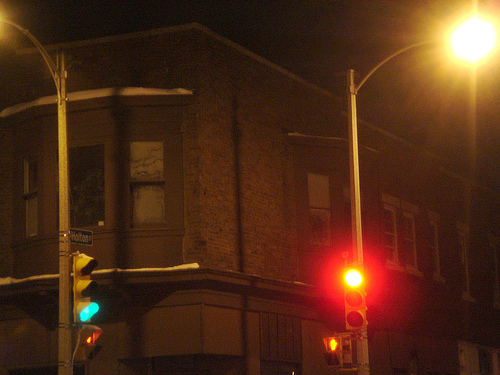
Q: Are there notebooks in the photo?
A: No, there are no notebooks.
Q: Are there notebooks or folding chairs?
A: No, there are no notebooks or folding chairs.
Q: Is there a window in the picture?
A: Yes, there is a window.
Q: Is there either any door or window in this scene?
A: Yes, there is a window.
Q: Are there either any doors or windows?
A: Yes, there is a window.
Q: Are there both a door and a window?
A: No, there is a window but no doors.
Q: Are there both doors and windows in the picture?
A: No, there is a window but no doors.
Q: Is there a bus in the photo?
A: No, there are no buses.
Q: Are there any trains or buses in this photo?
A: No, there are no buses or trains.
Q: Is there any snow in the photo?
A: Yes, there is snow.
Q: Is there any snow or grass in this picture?
A: Yes, there is snow.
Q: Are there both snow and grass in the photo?
A: No, there is snow but no grass.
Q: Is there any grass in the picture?
A: No, there is no grass.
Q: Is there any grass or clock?
A: No, there are no grass or clocks.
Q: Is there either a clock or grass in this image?
A: No, there are no grass or clocks.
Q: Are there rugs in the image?
A: No, there are no rugs.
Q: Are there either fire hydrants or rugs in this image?
A: No, there are no rugs or fire hydrants.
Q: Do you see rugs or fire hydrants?
A: No, there are no rugs or fire hydrants.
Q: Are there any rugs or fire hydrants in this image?
A: No, there are no rugs or fire hydrants.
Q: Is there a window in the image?
A: Yes, there is a window.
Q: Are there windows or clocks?
A: Yes, there is a window.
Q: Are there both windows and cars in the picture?
A: No, there is a window but no cars.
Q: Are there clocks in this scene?
A: No, there are no clocks.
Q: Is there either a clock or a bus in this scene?
A: No, there are no clocks or buses.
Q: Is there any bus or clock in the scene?
A: No, there are no clocks or buses.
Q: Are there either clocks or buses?
A: No, there are no clocks or buses.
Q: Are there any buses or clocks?
A: No, there are no clocks or buses.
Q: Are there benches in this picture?
A: No, there are no benches.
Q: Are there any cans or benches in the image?
A: No, there are no benches or cans.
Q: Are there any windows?
A: Yes, there is a window.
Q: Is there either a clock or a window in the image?
A: Yes, there is a window.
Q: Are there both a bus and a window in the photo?
A: No, there is a window but no buses.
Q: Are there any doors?
A: No, there are no doors.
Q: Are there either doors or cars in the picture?
A: No, there are no doors or cars.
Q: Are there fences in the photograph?
A: No, there are no fences.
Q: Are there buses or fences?
A: No, there are no fences or buses.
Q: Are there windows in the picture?
A: Yes, there is a window.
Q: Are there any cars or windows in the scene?
A: Yes, there is a window.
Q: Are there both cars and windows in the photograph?
A: No, there is a window but no cars.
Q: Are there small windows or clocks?
A: Yes, there is a small window.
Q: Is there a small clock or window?
A: Yes, there is a small window.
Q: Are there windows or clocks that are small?
A: Yes, the window is small.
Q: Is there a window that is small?
A: Yes, there is a small window.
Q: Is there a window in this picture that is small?
A: Yes, there is a window that is small.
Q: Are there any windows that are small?
A: Yes, there is a window that is small.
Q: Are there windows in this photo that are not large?
A: Yes, there is a small window.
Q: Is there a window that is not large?
A: Yes, there is a small window.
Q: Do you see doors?
A: No, there are no doors.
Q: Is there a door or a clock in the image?
A: No, there are no doors or clocks.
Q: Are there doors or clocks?
A: No, there are no doors or clocks.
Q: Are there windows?
A: Yes, there is a window.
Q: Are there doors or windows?
A: Yes, there is a window.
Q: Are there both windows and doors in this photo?
A: No, there is a window but no doors.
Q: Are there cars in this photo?
A: No, there are no cars.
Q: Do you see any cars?
A: No, there are no cars.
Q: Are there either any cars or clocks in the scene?
A: No, there are no cars or clocks.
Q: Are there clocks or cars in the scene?
A: No, there are no cars or clocks.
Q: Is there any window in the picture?
A: Yes, there is a window.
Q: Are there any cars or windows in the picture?
A: Yes, there is a window.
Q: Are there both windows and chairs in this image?
A: No, there is a window but no chairs.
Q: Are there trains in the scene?
A: No, there are no trains.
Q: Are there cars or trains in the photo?
A: No, there are no trains or cars.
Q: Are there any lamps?
A: Yes, there is a lamp.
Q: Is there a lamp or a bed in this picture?
A: Yes, there is a lamp.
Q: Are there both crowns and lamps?
A: No, there is a lamp but no crowns.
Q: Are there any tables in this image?
A: No, there are no tables.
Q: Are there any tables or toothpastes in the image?
A: No, there are no tables or toothpastes.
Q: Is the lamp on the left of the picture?
A: Yes, the lamp is on the left of the image.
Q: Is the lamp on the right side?
A: No, the lamp is on the left of the image.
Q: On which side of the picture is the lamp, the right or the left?
A: The lamp is on the left of the image.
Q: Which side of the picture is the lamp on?
A: The lamp is on the left of the image.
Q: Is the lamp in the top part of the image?
A: Yes, the lamp is in the top of the image.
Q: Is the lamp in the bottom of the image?
A: No, the lamp is in the top of the image.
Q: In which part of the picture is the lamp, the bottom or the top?
A: The lamp is in the top of the image.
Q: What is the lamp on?
A: The lamp is on the pole.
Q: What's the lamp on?
A: The lamp is on the pole.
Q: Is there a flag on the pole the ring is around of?
A: No, there is a lamp on the pole.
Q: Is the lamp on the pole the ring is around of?
A: Yes, the lamp is on the pole.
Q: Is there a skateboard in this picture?
A: No, there are no skateboards.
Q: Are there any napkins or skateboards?
A: No, there are no skateboards or napkins.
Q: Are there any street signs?
A: Yes, there is a street sign.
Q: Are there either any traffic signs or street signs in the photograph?
A: Yes, there is a street sign.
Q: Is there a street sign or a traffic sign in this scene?
A: Yes, there is a street sign.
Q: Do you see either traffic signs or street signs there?
A: Yes, there is a street sign.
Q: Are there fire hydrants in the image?
A: No, there are no fire hydrants.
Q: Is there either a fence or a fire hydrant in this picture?
A: No, there are no fire hydrants or fences.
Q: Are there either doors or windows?
A: Yes, there is a window.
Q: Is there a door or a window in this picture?
A: Yes, there is a window.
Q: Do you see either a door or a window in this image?
A: Yes, there is a window.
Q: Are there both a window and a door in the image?
A: No, there is a window but no doors.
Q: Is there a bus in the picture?
A: No, there are no buses.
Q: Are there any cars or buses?
A: No, there are no buses or cars.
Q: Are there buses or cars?
A: No, there are no buses or cars.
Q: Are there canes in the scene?
A: No, there are no canes.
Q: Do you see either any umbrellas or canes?
A: No, there are no canes or umbrellas.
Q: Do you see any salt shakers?
A: No, there are no salt shakers.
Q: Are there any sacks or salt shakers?
A: No, there are no salt shakers or sacks.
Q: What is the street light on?
A: The street light is on the pole.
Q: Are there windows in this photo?
A: Yes, there is a window.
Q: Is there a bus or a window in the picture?
A: Yes, there is a window.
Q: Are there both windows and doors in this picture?
A: No, there is a window but no doors.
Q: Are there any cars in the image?
A: No, there are no cars.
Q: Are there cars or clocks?
A: No, there are no cars or clocks.